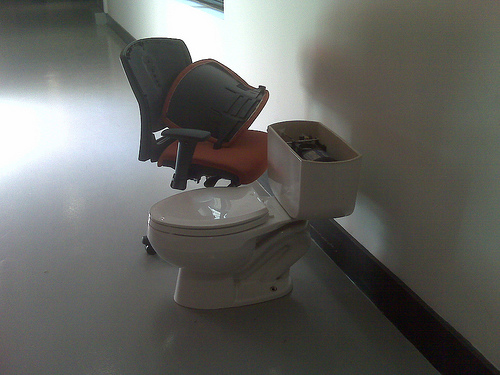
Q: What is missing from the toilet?
A: The lid for the tank.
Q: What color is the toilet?
A: White.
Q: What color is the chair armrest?
A: Black.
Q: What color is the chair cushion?
A: Red.